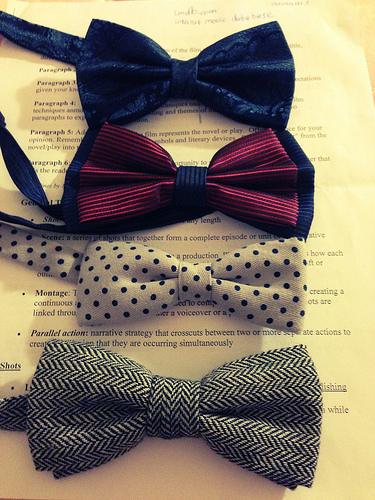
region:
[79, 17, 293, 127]
a blue damask bow tie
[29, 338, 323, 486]
a black and white houndstooth bow tie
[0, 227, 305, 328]
a gray and white polka dog bow tie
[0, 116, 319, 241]
a red and blue striped bow tie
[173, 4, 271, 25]
blue writing on white paper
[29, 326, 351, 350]
black ink text on a piece of paper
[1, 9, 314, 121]
The blue bow tie.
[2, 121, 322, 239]
The blue and burgundy bow tie.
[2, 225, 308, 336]
The white and black polka dot bow tie.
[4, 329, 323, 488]
The black and white bow tie.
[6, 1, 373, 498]
The paper under the bow ties.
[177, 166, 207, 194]
The knot on the burgundy and blue bow tie.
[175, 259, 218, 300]
The knot on the polka dot bow tie.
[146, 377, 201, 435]
The knot on the black and white bow tie.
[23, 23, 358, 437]
The letters on the paper under the bow ties.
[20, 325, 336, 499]
This is a tie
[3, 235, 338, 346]
This is a tie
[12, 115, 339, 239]
This is a tie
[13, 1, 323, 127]
This is a tie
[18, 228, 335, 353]
This is a bowtie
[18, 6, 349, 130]
This is a bowtie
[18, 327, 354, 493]
This is a bowtie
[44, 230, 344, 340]
This is a bowtie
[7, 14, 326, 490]
row of four bow ties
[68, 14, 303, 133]
dark blue felt bow tie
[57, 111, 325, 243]
red and blue bow tie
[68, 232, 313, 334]
polka dotted bow tie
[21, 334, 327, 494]
black and white herringbone tie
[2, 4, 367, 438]
typed paper under bow ties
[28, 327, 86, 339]
Parallel action in Italics on paper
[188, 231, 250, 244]
complete episode typed on paper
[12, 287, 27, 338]
row of two bullet points on paper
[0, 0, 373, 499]
a piece of white paper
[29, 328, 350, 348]
typed words on the paper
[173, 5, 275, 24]
written notes on the paper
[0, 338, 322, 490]
a black and white bowtie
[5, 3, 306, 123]
blue bow tie on the paper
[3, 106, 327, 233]
red and black bow on a paper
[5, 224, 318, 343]
tan and black bow on a paper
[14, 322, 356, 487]
tweed bow tie on a paper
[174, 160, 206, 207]
blue and black stripe on the middle of the bow tie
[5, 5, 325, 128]
a dark blue bow tie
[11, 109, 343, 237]
a red and blue striped bow tie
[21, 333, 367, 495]
a white and black patterned bow tie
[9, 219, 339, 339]
a small grey and black polka dotted bow tie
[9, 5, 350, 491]
several bow ties on a piece of paper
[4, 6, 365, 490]
a document with writing on it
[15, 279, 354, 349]
bulleted line items on a paper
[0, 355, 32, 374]
underlined heading on a paper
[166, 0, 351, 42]
handwritten words on a paper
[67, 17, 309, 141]
a bow tie that is blue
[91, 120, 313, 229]
a bow tie that is striped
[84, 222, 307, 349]
a bow tie that is polka dot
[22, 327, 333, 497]
a bow tie that is zig zagged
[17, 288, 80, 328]
words that are written in a book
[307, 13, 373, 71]
part of a page that is folded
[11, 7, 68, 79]
a piece of fabric that is blue